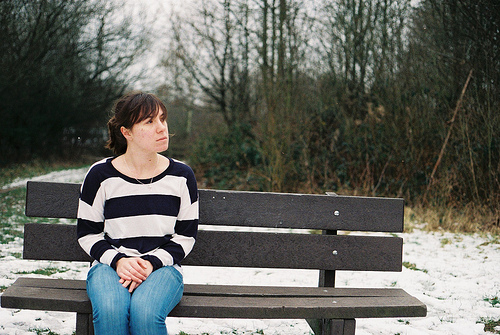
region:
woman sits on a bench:
[8, 86, 439, 333]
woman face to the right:
[57, 81, 213, 324]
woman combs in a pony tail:
[84, 84, 199, 208]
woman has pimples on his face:
[99, 93, 182, 174]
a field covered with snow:
[3, 97, 495, 334]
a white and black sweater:
[69, 150, 204, 272]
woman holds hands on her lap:
[73, 84, 205, 323]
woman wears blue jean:
[67, 75, 206, 332]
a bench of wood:
[3, 170, 432, 333]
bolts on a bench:
[326, 198, 343, 259]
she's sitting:
[73, 196, 113, 292]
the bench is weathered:
[228, 199, 258, 215]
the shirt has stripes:
[115, 197, 142, 231]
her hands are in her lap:
[111, 249, 151, 292]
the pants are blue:
[141, 293, 162, 321]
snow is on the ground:
[425, 253, 463, 288]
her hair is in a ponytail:
[103, 101, 130, 143]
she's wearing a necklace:
[126, 168, 158, 190]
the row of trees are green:
[347, 48, 471, 88]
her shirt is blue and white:
[120, 197, 166, 227]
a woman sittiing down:
[54, 88, 181, 317]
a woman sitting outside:
[47, 109, 301, 334]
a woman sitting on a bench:
[66, 101, 171, 330]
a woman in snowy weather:
[0, 38, 360, 334]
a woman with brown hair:
[53, 67, 253, 317]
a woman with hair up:
[87, 48, 290, 329]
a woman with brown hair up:
[42, 74, 264, 313]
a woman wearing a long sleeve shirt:
[28, 101, 257, 333]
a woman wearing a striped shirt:
[44, 81, 264, 331]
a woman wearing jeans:
[71, 35, 175, 334]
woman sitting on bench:
[75, 85, 187, 319]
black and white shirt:
[80, 163, 200, 265]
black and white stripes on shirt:
[75, 158, 193, 265]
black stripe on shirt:
[94, 192, 189, 217]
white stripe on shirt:
[103, 211, 176, 244]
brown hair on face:
[100, 93, 170, 155]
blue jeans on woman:
[75, 263, 179, 333]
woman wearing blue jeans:
[62, 223, 204, 333]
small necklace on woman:
[121, 160, 162, 188]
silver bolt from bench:
[331, 208, 342, 219]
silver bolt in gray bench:
[321, 204, 355, 226]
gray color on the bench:
[243, 204, 313, 221]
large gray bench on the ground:
[21, 175, 426, 321]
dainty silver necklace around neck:
[111, 163, 166, 195]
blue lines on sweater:
[107, 168, 195, 180]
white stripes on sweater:
[114, 217, 171, 239]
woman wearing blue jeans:
[88, 257, 192, 326]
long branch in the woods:
[429, 102, 463, 201]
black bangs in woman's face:
[121, 87, 168, 124]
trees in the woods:
[203, 89, 376, 156]